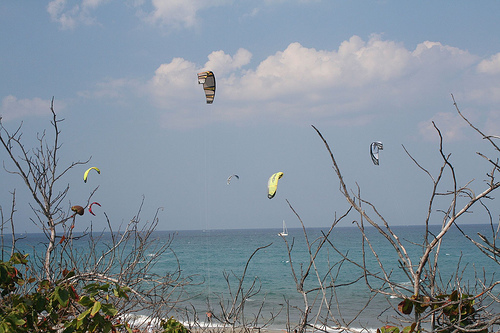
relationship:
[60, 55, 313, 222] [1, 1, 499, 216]
kites in sky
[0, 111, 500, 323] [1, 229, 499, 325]
trees near water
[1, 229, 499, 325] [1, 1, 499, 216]
water under sky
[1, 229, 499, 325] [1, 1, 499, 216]
water below sky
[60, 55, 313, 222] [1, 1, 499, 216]
kites below sky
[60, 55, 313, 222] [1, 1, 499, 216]
kites under sky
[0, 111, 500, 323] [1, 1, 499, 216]
trees under sky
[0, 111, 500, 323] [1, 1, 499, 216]
trees below sky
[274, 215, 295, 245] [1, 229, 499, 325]
boat in water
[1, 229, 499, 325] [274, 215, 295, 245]
water below boat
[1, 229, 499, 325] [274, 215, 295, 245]
water under boat